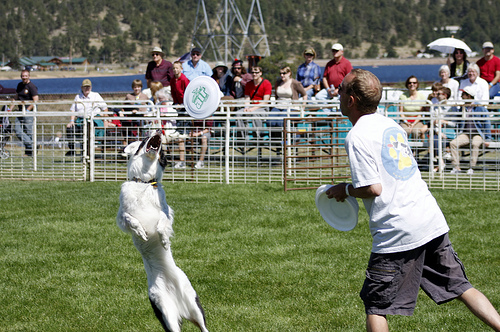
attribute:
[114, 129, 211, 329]
dog — black and white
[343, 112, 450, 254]
shirt — white 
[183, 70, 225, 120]
frisbee — white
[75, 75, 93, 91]
hat — tan 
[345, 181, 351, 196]
band — white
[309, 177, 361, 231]
white frisbees — white 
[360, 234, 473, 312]
cargo shorts — gray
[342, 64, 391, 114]
hair — brown 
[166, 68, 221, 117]
frisbee — white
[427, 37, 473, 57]
umbrella —  white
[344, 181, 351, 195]
band — white 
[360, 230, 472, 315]
pants — grey 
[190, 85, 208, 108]
logo — blue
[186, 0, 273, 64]
pylon — electric, metal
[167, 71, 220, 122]
frisbee — white 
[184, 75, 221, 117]
frisbee — white 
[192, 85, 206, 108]
print — green 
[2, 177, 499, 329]
grass — short, green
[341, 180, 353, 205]
bracelet — white